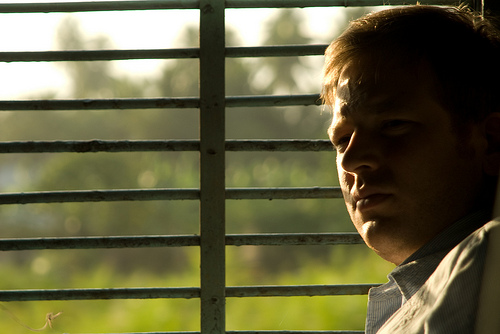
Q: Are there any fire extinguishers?
A: No, there are no fire extinguishers.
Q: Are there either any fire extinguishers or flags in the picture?
A: No, there are no fire extinguishers or flags.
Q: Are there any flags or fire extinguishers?
A: No, there are no fire extinguishers or flags.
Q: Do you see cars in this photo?
A: No, there are no cars.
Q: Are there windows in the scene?
A: Yes, there is a window.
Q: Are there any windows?
A: Yes, there is a window.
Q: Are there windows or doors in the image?
A: Yes, there is a window.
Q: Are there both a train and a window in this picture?
A: No, there is a window but no trains.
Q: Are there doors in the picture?
A: No, there are no doors.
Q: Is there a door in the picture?
A: No, there are no doors.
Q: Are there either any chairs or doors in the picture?
A: No, there are no doors or chairs.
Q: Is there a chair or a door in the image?
A: No, there are no doors or chairs.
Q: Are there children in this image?
A: No, there are no children.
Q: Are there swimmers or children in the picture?
A: No, there are no children or swimmers.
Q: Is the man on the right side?
A: Yes, the man is on the right of the image.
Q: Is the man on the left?
A: No, the man is on the right of the image.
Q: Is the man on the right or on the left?
A: The man is on the right of the image.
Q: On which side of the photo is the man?
A: The man is on the right of the image.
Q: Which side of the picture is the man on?
A: The man is on the right of the image.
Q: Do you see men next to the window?
A: Yes, there is a man next to the window.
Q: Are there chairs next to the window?
A: No, there is a man next to the window.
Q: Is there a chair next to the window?
A: No, there is a man next to the window.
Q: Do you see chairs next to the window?
A: No, there is a man next to the window.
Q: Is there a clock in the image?
A: No, there are no clocks.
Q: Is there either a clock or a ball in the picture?
A: No, there are no clocks or balls.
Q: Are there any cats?
A: No, there are no cats.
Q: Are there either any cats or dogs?
A: No, there are no cats or dogs.